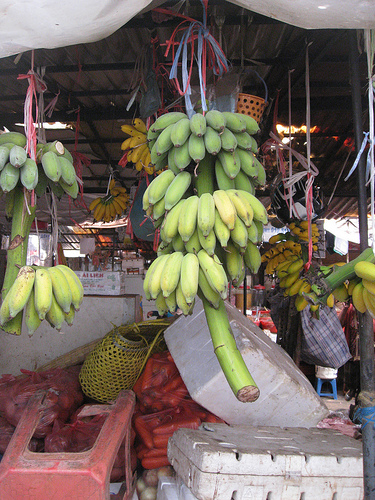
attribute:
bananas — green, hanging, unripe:
[5, 116, 267, 345]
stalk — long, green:
[4, 117, 42, 335]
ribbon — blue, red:
[169, 14, 224, 111]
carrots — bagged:
[131, 347, 222, 466]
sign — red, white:
[79, 273, 132, 300]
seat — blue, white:
[317, 363, 334, 399]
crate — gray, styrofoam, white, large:
[149, 427, 362, 499]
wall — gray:
[8, 293, 141, 379]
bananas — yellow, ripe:
[82, 112, 153, 224]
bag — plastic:
[8, 367, 98, 455]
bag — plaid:
[301, 306, 355, 366]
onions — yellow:
[126, 467, 175, 497]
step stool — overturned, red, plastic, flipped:
[2, 397, 136, 497]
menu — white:
[256, 219, 327, 261]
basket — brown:
[236, 67, 267, 122]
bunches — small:
[89, 185, 134, 227]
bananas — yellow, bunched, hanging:
[263, 225, 371, 312]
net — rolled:
[2, 3, 374, 63]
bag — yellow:
[83, 321, 163, 401]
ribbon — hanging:
[284, 27, 325, 231]